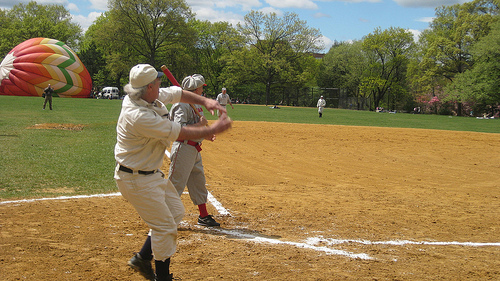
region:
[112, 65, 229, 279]
old man playing catcher standing up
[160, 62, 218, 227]
hitter with a red bat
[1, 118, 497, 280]
dirt baseball field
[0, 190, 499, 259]
white chalk lines in the dirt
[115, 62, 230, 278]
players wearing replica baseball uniforms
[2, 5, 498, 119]
green trees lining the park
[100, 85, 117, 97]
white van by the balloon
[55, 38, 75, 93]
green stripe on the balloon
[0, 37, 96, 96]
a large hot air balloon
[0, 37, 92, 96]
a red white yellow green balloon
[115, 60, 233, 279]
a baseball umpire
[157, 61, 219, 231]
a baseball player at bat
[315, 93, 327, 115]
a baseball player in field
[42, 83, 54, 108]
a baseball player in field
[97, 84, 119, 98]
a white van in distance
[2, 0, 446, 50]
a cloudy blue sky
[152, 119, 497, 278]
a dirt baseball field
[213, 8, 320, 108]
large green tree in distance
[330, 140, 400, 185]
the dirt is brown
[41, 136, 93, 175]
a field of green grass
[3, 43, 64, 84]
a hot air ballon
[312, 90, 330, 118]
a person standing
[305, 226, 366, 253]
a white line on the field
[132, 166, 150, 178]
a black belt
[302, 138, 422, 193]
the dirt is brown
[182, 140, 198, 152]
a red belt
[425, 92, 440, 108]
purple leaves on the tree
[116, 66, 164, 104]
head of a person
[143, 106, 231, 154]
arm of a person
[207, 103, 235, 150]
hand of a person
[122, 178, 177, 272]
leg of a person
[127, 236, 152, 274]
feet of a person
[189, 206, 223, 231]
feet of a person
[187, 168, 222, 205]
leg of a person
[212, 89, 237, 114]
finger of a person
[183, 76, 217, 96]
head of a person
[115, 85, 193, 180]
body of a person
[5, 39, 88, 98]
a large hot air balloon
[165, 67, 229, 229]
a baseball player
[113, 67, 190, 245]
a man wearing a white hat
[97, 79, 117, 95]
a white van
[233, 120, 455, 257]
dirt on the baseball field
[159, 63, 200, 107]
a baseball bat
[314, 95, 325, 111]
a person standing in the grass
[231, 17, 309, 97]
a large tree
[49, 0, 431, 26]
the sky above the trees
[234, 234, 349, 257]
white lines painted on the dirt